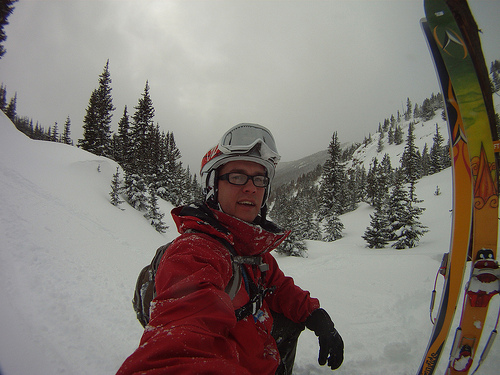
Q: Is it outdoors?
A: Yes, it is outdoors.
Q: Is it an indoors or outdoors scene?
A: It is outdoors.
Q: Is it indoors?
A: No, it is outdoors.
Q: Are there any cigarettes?
A: No, there are no cigarettes.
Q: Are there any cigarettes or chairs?
A: No, there are no cigarettes or chairs.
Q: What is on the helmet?
A: The glasses are on the helmet.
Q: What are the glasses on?
A: The glasses are on the helmet.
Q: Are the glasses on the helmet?
A: Yes, the glasses are on the helmet.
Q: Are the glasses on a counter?
A: No, the glasses are on the helmet.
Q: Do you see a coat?
A: Yes, there is a coat.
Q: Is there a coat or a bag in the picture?
A: Yes, there is a coat.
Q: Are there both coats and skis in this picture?
A: Yes, there are both a coat and skis.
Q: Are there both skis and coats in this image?
A: Yes, there are both a coat and skis.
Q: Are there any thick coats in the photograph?
A: Yes, there is a thick coat.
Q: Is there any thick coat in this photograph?
A: Yes, there is a thick coat.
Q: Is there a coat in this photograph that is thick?
A: Yes, there is a thick coat.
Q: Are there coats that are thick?
A: Yes, there is a coat that is thick.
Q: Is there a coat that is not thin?
A: Yes, there is a thick coat.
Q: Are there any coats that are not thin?
A: Yes, there is a thick coat.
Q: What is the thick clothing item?
A: The clothing item is a coat.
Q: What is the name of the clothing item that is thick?
A: The clothing item is a coat.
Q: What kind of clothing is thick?
A: The clothing is a coat.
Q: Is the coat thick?
A: Yes, the coat is thick.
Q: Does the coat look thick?
A: Yes, the coat is thick.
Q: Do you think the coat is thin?
A: No, the coat is thick.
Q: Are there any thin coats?
A: No, there is a coat but it is thick.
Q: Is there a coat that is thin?
A: No, there is a coat but it is thick.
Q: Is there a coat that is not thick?
A: No, there is a coat but it is thick.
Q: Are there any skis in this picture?
A: Yes, there are skis.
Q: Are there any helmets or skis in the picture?
A: Yes, there are skis.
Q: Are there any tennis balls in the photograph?
A: No, there are no tennis balls.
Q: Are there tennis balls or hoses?
A: No, there are no tennis balls or hoses.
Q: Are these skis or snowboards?
A: These are skis.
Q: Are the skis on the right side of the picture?
A: Yes, the skis are on the right of the image.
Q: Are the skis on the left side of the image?
A: No, the skis are on the right of the image.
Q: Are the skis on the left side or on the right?
A: The skis are on the right of the image.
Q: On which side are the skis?
A: The skis are on the right of the image.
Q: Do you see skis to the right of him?
A: Yes, there are skis to the right of the man.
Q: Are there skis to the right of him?
A: Yes, there are skis to the right of the man.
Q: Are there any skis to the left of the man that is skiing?
A: No, the skis are to the right of the man.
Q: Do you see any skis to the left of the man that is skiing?
A: No, the skis are to the right of the man.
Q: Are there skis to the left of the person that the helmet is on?
A: No, the skis are to the right of the man.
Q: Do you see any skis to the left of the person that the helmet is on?
A: No, the skis are to the right of the man.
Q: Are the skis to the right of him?
A: Yes, the skis are to the right of the man.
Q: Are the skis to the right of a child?
A: No, the skis are to the right of the man.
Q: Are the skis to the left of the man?
A: No, the skis are to the right of the man.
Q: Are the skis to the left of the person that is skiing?
A: No, the skis are to the right of the man.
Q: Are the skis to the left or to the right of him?
A: The skis are to the right of the man.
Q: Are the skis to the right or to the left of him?
A: The skis are to the right of the man.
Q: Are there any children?
A: No, there are no children.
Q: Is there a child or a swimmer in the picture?
A: No, there are no children or swimmers.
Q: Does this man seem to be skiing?
A: Yes, the man is skiing.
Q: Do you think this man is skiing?
A: Yes, the man is skiing.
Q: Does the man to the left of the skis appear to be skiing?
A: Yes, the man is skiing.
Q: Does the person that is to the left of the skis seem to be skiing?
A: Yes, the man is skiing.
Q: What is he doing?
A: The man is skiing.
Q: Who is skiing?
A: The man is skiing.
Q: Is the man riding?
A: No, the man is skiing.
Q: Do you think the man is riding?
A: No, the man is skiing.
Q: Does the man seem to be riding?
A: No, the man is skiing.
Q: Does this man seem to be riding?
A: No, the man is skiing.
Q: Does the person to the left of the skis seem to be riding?
A: No, the man is skiing.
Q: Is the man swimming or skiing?
A: The man is skiing.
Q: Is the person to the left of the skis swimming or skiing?
A: The man is skiing.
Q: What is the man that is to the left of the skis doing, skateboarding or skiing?
A: The man is skiing.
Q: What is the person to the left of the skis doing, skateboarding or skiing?
A: The man is skiing.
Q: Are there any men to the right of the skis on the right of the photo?
A: No, the man is to the left of the skis.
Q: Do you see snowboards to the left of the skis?
A: No, there is a man to the left of the skis.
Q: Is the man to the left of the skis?
A: Yes, the man is to the left of the skis.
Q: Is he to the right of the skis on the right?
A: No, the man is to the left of the skis.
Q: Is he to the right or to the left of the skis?
A: The man is to the left of the skis.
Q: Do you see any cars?
A: No, there are no cars.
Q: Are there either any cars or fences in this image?
A: No, there are no cars or fences.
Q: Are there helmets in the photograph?
A: Yes, there is a helmet.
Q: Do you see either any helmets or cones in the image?
A: Yes, there is a helmet.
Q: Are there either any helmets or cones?
A: Yes, there is a helmet.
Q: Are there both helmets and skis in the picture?
A: Yes, there are both a helmet and skis.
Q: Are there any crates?
A: No, there are no crates.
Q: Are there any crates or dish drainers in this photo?
A: No, there are no crates or dish drainers.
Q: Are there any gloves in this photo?
A: Yes, there are gloves.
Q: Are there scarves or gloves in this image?
A: Yes, there are gloves.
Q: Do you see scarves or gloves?
A: Yes, there are gloves.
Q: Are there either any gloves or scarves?
A: Yes, there are gloves.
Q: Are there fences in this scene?
A: No, there are no fences.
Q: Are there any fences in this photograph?
A: No, there are no fences.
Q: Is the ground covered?
A: Yes, the ground is covered.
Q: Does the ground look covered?
A: Yes, the ground is covered.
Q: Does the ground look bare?
A: No, the ground is covered.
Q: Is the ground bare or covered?
A: The ground is covered.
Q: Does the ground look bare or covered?
A: The ground is covered.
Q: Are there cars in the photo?
A: No, there are no cars.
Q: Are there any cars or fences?
A: No, there are no cars or fences.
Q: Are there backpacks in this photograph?
A: Yes, there is a backpack.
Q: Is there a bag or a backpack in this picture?
A: Yes, there is a backpack.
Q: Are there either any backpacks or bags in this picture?
A: Yes, there is a backpack.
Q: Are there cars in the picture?
A: No, there are no cars.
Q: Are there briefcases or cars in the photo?
A: No, there are no cars or briefcases.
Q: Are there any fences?
A: No, there are no fences.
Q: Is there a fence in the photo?
A: No, there are no fences.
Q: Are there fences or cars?
A: No, there are no fences or cars.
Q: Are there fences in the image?
A: No, there are no fences.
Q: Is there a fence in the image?
A: No, there are no fences.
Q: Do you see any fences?
A: No, there are no fences.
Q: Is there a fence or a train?
A: No, there are no fences or trains.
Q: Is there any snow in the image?
A: Yes, there is snow.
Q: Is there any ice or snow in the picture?
A: Yes, there is snow.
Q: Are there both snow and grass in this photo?
A: No, there is snow but no grass.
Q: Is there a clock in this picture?
A: No, there are no clocks.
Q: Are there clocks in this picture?
A: No, there are no clocks.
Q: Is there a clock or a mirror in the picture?
A: No, there are no clocks or mirrors.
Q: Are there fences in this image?
A: No, there are no fences.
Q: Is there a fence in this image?
A: No, there are no fences.